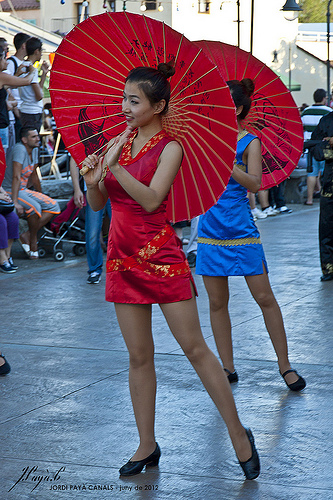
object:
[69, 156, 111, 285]
guy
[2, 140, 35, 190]
shirt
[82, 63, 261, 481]
woman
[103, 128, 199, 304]
dress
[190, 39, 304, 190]
umbrella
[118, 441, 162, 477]
shoes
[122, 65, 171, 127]
head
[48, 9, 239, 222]
umbrella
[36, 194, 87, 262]
carriage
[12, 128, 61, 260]
guy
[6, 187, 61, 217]
shorts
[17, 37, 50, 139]
guy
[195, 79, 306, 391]
woman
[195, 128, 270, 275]
dress